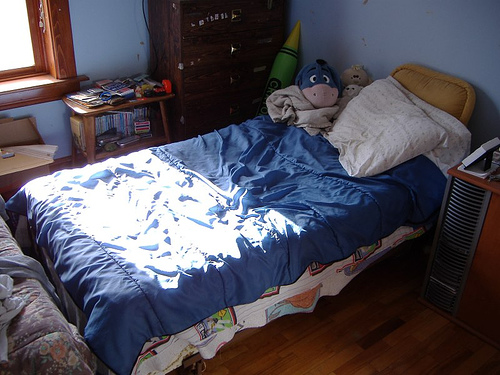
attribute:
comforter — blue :
[39, 121, 441, 334]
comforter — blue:
[6, 110, 442, 371]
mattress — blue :
[15, 110, 448, 356]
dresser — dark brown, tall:
[167, 11, 297, 141]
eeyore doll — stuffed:
[290, 52, 341, 111]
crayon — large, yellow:
[254, 19, 305, 112]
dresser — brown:
[146, 2, 294, 143]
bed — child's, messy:
[0, 107, 454, 370]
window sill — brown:
[0, 71, 93, 111]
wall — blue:
[284, 2, 496, 152]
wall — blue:
[0, 2, 150, 158]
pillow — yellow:
[390, 57, 480, 128]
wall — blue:
[0, 2, 152, 174]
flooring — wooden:
[189, 258, 499, 374]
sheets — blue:
[0, 106, 450, 366]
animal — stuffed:
[294, 54, 339, 108]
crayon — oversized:
[265, 20, 303, 90]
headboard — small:
[389, 58, 477, 127]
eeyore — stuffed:
[294, 53, 344, 113]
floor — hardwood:
[239, 270, 396, 365]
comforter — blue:
[88, 157, 306, 267]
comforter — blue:
[80, 188, 190, 288]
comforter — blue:
[256, 169, 320, 230]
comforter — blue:
[211, 125, 296, 233]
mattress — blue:
[87, 189, 271, 291]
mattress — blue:
[219, 149, 313, 220]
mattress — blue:
[76, 187, 146, 296]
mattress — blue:
[216, 123, 315, 258]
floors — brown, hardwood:
[265, 311, 442, 371]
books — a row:
[94, 107, 153, 137]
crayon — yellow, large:
[259, 19, 304, 116]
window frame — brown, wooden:
[0, 0, 82, 117]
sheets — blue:
[22, 138, 390, 319]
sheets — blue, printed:
[33, 111, 408, 299]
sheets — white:
[129, 227, 449, 362]